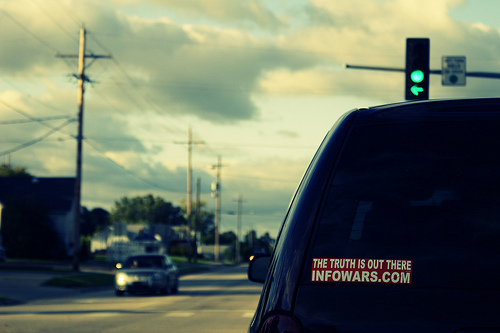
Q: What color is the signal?
A: Green.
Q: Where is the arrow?
A: On the signal.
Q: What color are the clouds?
A: White.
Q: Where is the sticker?
A: On the rear window.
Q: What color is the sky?
A: Blue.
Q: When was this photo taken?
A: Daytime.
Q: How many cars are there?
A: Two.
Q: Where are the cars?
A: In the street.